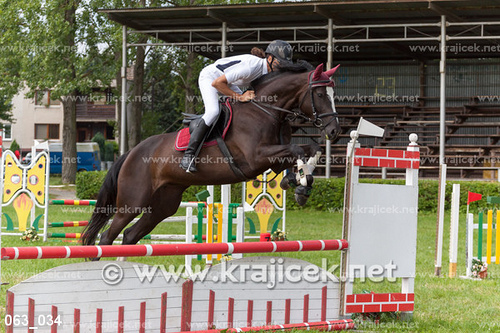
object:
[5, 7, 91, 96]
tree leaves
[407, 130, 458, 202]
ground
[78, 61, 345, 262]
horse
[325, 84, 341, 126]
mark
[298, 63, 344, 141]
horse's head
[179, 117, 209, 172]
boot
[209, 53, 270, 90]
shirt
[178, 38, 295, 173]
jokey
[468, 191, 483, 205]
flag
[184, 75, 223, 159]
leg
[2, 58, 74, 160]
building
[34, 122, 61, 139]
window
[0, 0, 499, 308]
poles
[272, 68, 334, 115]
ground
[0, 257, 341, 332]
panels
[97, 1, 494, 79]
roof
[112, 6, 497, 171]
metal supports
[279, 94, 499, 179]
stands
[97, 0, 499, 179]
bleachers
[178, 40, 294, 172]
rider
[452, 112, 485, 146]
section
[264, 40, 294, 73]
helmet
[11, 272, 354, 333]
vertical lines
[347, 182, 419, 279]
white panel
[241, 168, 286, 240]
butterfly support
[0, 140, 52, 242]
butterfly support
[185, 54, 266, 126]
outfit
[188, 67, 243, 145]
pants